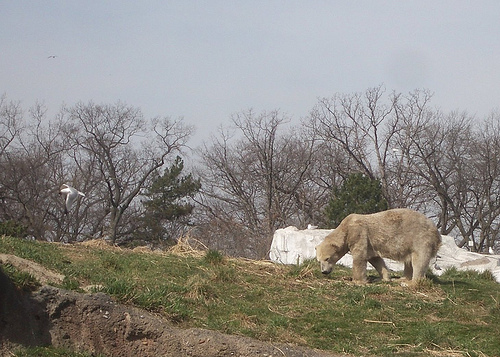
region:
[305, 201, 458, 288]
White bear standing in a field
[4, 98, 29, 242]
LArge brown tree with no leaves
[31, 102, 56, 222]
LArge brown tree with no leaves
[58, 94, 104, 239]
LArge brown tree with no leaves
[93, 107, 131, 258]
LArge brown tree with no leaves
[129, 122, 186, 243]
LArge brown tree with no leaves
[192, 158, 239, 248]
LArge brown tree with no leaves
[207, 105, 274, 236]
LArge brown tree with no leaves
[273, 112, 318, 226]
LArge brown tree with no leaves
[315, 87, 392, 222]
LArge brown tree with no leaves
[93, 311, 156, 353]
brown dirt like area on ground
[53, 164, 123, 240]
white bird in sky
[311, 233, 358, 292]
white polar bear looking down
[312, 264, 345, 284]
black nose of white bear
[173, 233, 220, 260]
yellow straw under tree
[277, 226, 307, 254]
white patch of snow behind bear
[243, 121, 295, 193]
brown bare tree with no leaves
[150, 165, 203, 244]
tree in distance with green leaves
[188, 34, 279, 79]
grey area of sky in photo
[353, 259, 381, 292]
front left paw of bear in photo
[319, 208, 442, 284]
A polar bear eating the grass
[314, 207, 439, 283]
The polar bear has white fur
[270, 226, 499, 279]
A large rock near the polar bear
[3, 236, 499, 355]
Grass below the polar bear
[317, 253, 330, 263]
The eyes of the polar bear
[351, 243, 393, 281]
The front legs of the polar bear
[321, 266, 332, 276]
The nose of the polar bear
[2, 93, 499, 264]
Trees near the polar bear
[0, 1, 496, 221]
The sky above the polar bear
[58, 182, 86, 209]
A bird near the polar bear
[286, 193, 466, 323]
this is a polar bear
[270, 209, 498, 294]
this is the ice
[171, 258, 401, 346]
this is the grass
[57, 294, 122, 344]
this is the dirt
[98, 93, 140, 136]
this is a branch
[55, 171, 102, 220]
this is a bird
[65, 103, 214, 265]
this is a tree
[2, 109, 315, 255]
these are the trees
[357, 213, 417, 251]
this is the fur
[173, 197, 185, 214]
these are the leaves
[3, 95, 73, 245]
tree at edge of forest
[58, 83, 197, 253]
tree at edge of forest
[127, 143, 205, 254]
tree at edge of forest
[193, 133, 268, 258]
tree at edge of forest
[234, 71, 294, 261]
tree at edge of forest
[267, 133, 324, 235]
tree at edge of forest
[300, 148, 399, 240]
tree at edge of forest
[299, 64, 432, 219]
tree at edge of forest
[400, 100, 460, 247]
tree at edge of forest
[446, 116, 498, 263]
tree at edge of forest